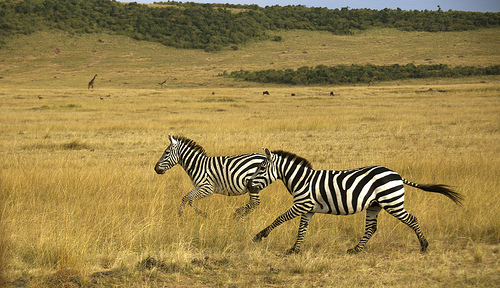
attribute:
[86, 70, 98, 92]
giraffe — far away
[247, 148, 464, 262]
zebra — running, stripped, black, white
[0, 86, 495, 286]
grass — dry, green, tall, dried, yellow, brown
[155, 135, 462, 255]
zebras — running, black, white, stripped, walking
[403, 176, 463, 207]
tail — up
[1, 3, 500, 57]
bushes — green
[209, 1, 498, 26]
sky — light blue, blue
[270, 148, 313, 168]
mane — short, dark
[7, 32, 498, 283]
field — grassy, dry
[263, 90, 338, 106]
animals — small, grazing, pasting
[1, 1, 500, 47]
hill — large, green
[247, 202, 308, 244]
leg — stepping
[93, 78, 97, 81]
neck — tall